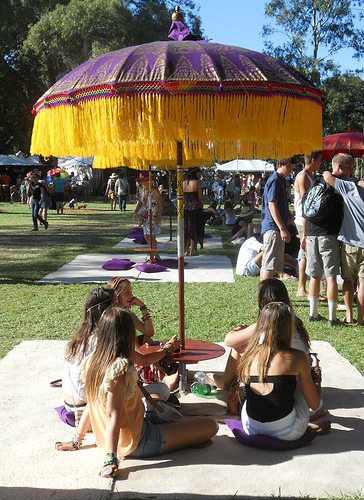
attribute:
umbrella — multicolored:
[33, 38, 271, 139]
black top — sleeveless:
[227, 362, 322, 429]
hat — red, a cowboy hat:
[131, 166, 161, 186]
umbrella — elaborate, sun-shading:
[30, 23, 292, 193]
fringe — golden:
[30, 112, 315, 149]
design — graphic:
[305, 180, 328, 229]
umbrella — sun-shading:
[25, 44, 269, 202]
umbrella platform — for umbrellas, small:
[128, 329, 233, 375]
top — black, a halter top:
[230, 365, 302, 427]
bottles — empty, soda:
[183, 365, 217, 399]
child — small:
[60, 191, 77, 214]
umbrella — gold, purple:
[23, 34, 347, 180]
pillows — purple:
[109, 235, 163, 273]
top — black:
[228, 359, 313, 425]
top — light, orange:
[86, 369, 143, 453]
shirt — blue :
[260, 170, 284, 234]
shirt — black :
[305, 171, 352, 235]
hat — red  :
[136, 173, 151, 181]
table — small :
[138, 338, 226, 361]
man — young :
[308, 155, 353, 323]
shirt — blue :
[263, 174, 290, 232]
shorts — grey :
[261, 229, 290, 270]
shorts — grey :
[301, 234, 338, 276]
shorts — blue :
[246, 259, 259, 276]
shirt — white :
[235, 238, 263, 275]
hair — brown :
[233, 304, 298, 390]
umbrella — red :
[317, 132, 362, 156]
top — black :
[242, 372, 297, 420]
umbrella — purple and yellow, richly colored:
[28, 7, 321, 166]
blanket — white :
[3, 339, 363, 497]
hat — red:
[133, 168, 153, 181]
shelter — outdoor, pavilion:
[209, 155, 277, 172]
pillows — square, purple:
[102, 238, 192, 281]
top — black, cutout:
[226, 353, 323, 429]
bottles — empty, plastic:
[180, 357, 225, 398]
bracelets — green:
[94, 444, 130, 479]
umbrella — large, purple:
[42, 32, 267, 162]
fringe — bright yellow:
[33, 97, 332, 179]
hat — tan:
[101, 173, 120, 182]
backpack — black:
[298, 179, 345, 230]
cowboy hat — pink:
[134, 168, 150, 183]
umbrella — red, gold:
[322, 123, 362, 163]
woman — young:
[232, 300, 322, 446]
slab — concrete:
[1, 334, 357, 498]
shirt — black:
[243, 372, 300, 424]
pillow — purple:
[219, 416, 321, 453]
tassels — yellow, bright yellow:
[28, 87, 329, 171]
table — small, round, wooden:
[134, 334, 227, 364]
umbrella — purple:
[27, 2, 328, 112]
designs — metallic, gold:
[165, 51, 205, 82]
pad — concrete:
[3, 335, 363, 497]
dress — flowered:
[135, 184, 162, 238]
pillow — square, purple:
[100, 257, 136, 271]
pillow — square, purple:
[135, 261, 168, 274]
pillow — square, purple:
[158, 256, 187, 270]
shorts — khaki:
[298, 232, 341, 280]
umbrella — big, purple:
[25, 3, 330, 392]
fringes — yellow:
[23, 91, 326, 174]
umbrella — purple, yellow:
[27, 4, 329, 179]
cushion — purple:
[102, 258, 132, 270]